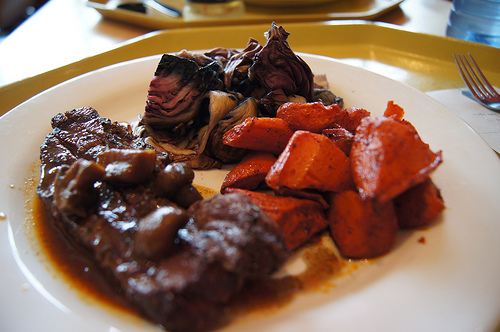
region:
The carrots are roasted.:
[227, 110, 434, 255]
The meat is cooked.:
[35, 110, 265, 316]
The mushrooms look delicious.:
[52, 140, 202, 252]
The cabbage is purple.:
[141, 35, 321, 140]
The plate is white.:
[0, 45, 497, 325]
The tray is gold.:
[5, 22, 495, 322]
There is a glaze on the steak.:
[35, 181, 286, 316]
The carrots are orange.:
[210, 93, 453, 261]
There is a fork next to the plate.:
[453, 46, 498, 111]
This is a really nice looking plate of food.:
[0, 31, 498, 329]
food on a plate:
[0, 20, 497, 330]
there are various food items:
[38, 24, 445, 329]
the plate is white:
[0, 48, 499, 330]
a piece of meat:
[42, 108, 280, 330]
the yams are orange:
[222, 100, 444, 260]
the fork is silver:
[455, 54, 498, 111]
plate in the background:
[85, 0, 408, 18]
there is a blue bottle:
[446, 3, 498, 46]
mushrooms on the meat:
[57, 147, 194, 256]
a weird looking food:
[146, 22, 341, 172]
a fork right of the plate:
[453, 48, 498, 110]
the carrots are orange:
[220, 101, 437, 256]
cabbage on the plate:
[138, 22, 335, 184]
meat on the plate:
[35, 100, 290, 330]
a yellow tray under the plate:
[1, 15, 496, 126]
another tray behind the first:
[75, 0, 409, 31]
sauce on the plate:
[245, 240, 366, 308]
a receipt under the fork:
[425, 65, 498, 143]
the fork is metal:
[447, 48, 497, 109]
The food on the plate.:
[54, 55, 434, 328]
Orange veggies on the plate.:
[240, 114, 431, 266]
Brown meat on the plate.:
[34, 119, 265, 326]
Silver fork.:
[449, 51, 496, 101]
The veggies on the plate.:
[150, 49, 297, 152]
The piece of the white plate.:
[0, 111, 21, 202]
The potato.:
[347, 121, 442, 204]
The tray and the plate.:
[90, 0, 415, 20]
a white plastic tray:
[0, 20, 499, 157]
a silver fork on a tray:
[451, 52, 498, 112]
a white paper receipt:
[423, 83, 498, 153]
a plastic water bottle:
[442, 1, 499, 48]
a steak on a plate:
[35, 105, 288, 326]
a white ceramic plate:
[1, 45, 498, 330]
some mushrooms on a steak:
[52, 143, 197, 256]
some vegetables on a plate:
[140, 13, 447, 269]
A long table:
[1, 0, 454, 86]